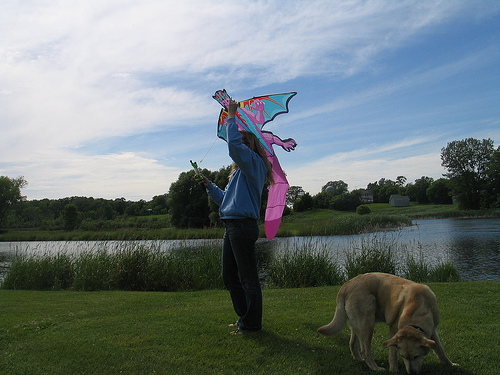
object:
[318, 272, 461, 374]
dog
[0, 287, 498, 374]
grass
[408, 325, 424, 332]
collar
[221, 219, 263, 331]
pants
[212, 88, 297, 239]
kite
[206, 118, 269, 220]
shirt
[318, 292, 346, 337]
tail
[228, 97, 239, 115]
hand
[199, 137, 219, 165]
string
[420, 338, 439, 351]
ear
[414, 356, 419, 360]
eyes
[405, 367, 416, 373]
nose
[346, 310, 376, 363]
legs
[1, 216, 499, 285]
water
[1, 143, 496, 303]
background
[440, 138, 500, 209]
trees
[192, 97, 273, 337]
girl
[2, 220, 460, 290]
reeds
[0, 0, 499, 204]
sky